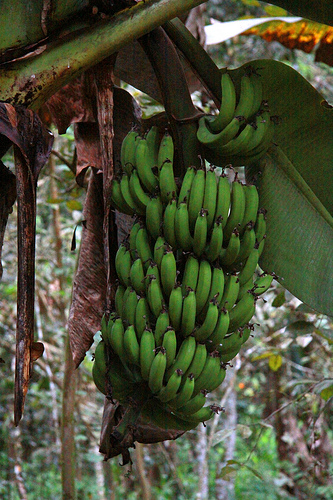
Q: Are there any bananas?
A: Yes, there is a banana.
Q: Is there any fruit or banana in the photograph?
A: Yes, there is a banana.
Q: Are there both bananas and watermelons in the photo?
A: No, there is a banana but no watermelons.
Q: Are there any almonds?
A: No, there are no almonds.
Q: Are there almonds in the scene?
A: No, there are no almonds.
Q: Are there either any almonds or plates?
A: No, there are no almonds or plates.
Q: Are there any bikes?
A: No, there are no bikes.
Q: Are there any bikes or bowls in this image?
A: No, there are no bikes or bowls.